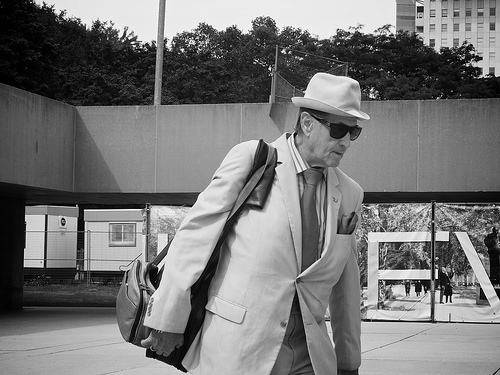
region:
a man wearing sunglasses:
[277, 47, 382, 215]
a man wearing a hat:
[258, 64, 393, 221]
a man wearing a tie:
[251, 63, 401, 300]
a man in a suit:
[178, 79, 422, 374]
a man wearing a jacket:
[178, 75, 410, 372]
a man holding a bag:
[102, 76, 388, 364]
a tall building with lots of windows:
[362, 2, 494, 109]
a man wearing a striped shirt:
[242, 9, 369, 303]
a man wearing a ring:
[78, 95, 388, 365]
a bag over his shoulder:
[77, 106, 297, 350]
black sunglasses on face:
[304, 111, 364, 142]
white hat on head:
[289, 70, 371, 122]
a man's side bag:
[113, 140, 278, 355]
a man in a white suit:
[111, 68, 371, 373]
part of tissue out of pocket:
[336, 211, 361, 239]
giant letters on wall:
[364, 228, 498, 320]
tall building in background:
[395, 0, 498, 78]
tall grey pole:
[153, 0, 166, 106]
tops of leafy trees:
[0, 0, 498, 103]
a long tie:
[298, 166, 322, 275]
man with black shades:
[301, 101, 378, 172]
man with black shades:
[301, 124, 398, 211]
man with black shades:
[265, 111, 359, 152]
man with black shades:
[268, 88, 409, 206]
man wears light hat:
[293, 54, 365, 116]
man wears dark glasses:
[298, 111, 367, 163]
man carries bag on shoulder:
[87, 167, 296, 352]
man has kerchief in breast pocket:
[338, 192, 376, 252]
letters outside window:
[359, 221, 497, 340]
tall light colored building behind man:
[367, 14, 497, 81]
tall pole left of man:
[141, 1, 179, 97]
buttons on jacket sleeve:
[133, 286, 168, 327]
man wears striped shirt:
[287, 153, 326, 283]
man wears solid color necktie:
[300, 171, 333, 278]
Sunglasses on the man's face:
[307, 110, 370, 149]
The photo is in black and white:
[29, 12, 495, 360]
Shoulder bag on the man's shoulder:
[95, 136, 283, 351]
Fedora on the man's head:
[284, 66, 381, 126]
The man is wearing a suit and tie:
[99, 1, 413, 371]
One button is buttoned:
[274, 268, 312, 296]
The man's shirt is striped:
[267, 128, 336, 266]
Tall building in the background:
[397, 2, 499, 93]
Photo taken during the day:
[6, 10, 492, 369]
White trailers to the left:
[22, 193, 156, 296]